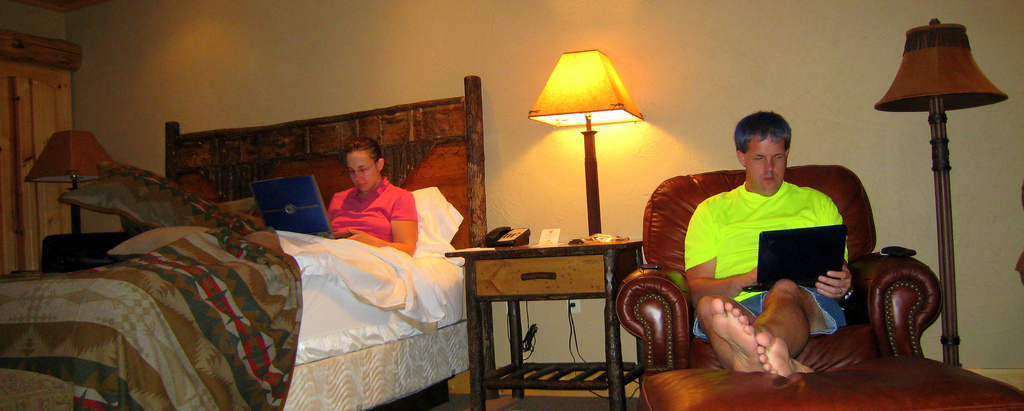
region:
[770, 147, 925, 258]
The man is sitting down using a laptop.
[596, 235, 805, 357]
The man is sitting down using a laptop.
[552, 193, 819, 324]
The man is sitting down using a laptop.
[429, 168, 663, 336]
The man is sitting down using a laptop.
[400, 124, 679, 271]
The man is sitting down using a laptop.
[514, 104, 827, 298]
The man is sitting down using a laptop.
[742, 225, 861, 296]
The laptop is black.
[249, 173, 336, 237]
The laptop is blue.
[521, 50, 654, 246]
The light is on.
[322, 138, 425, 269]
The woman is in the bed.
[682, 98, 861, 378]
Man is in the chair.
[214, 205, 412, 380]
Blanket is pulled back.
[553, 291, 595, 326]
Cord is plugged into the wall.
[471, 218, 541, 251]
Phone is on the table.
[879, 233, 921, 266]
Remote is on the chair arm.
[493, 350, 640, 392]
Rack is under the table.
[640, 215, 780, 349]
The man is sitting down using a laptop.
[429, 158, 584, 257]
The man is sitting down using a laptop.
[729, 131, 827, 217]
The man is sitting down using a laptop.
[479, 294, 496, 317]
The man is sitting down using a laptop.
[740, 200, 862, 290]
Man is holding a laptop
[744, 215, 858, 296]
Man holding a black laptop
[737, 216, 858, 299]
Man is holding a black laptop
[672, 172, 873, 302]
Man wearing a yellow shirt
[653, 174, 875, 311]
Man is wearing a yellow shirt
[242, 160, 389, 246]
Woman is on a laptop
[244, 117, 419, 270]
Woman is sitting in bed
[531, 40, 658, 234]
a tall table lamp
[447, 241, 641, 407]
a side table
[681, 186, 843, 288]
a man's green short sleeve shirt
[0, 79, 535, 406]
a large bed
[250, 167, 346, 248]
a blue and gray laptop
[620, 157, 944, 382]
a leather chair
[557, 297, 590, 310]
a white wall outlet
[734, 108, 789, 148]
short cut gray hair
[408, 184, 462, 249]
a white bed pillow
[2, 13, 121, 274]
A wooden chest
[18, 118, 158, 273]
The lamp to the left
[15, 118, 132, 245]
A lamp to the left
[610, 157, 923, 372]
A chair that you sit in.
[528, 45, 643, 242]
A lamp on a table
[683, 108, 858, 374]
A man using a laptop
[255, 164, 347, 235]
A laptop on a bed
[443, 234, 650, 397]
A table in a bedroom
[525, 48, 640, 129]
A shade on a table lamp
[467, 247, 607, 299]
A drawer on a table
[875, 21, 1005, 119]
A shade on a floor lamp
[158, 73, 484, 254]
A head board on a bed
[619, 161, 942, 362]
A chair in a bedroom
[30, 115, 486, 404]
a large bed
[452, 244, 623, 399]
a small end table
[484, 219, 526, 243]
a black telephone on the table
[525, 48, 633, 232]
a lamp on the table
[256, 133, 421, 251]
a woman laying in the bed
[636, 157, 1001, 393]
a large brown chair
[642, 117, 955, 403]
a man in a green shirt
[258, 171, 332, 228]
a blue laptop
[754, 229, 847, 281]
a black laptop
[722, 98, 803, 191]
the head of a man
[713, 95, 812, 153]
the hair of a man